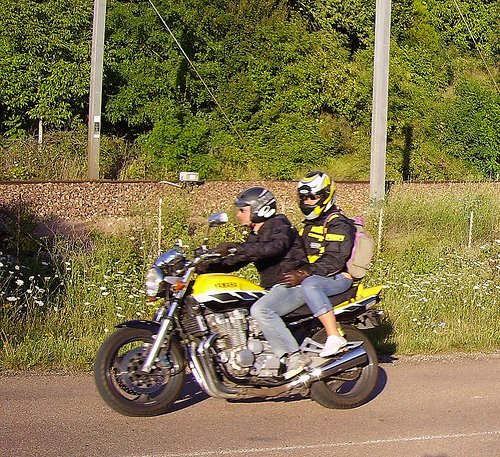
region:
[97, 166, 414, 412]
couple on a motorcycle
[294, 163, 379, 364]
woman with a brown backpack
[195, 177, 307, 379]
man in black helmet and blue jeans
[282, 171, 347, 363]
woman wearing brown leather gloves and blue jeans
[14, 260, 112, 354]
white flowers growing next to highway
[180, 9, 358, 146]
forest of green trees next to train tracks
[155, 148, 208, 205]
metal electrical box on the ground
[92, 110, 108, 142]
black and white sign on wooden pole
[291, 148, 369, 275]
woman in yellow and black motorcycle helmet and jacket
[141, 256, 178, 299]
shiny headlight on front of motorcycle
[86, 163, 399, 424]
A man and a woman are on a motorcycle.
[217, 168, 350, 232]
Both riders are wearing helmets.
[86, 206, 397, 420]
The motorcycle's colors are yellow and black.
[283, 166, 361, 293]
The woman's helmet and jacket colors match those of the motorcycle.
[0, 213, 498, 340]
Flowers are growing on the side of the road.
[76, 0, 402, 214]
Two poles are in the background.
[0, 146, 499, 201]
Railroad tracks are in the background.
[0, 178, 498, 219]
Gravel rocks are besides the tracks.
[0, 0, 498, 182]
Trees are in the background.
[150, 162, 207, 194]
A box of some kind is beside the railroad tracks.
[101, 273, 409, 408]
motorcycle on the road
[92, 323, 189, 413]
black with chrome motorcycle tire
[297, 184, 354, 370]
woman riding on back on motorcycle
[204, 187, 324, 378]
man riding a motorcycle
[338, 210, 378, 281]
tan and pink backpack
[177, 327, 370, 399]
chrome motorcycle muffler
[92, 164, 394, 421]
two people riding on a motorcycle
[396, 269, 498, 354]
small white wild flowers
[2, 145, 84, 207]
train rails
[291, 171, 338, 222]
woman's riding helmet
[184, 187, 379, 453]
Two people riding on a motorcycle.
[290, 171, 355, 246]
A person with a helmet on their head.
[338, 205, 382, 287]
The person on the back of the bike has on backpack.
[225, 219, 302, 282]
The man has on a black jacket.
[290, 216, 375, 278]
The lady has on a yellow and black jacket.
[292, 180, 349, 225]
The helmet is yellow and black.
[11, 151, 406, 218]
The tracks is on the other side of the road.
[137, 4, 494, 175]
A lot of trees and bushes on the side of the track.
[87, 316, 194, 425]
The motorcycle has a black wheel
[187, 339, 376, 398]
The muffler is long and chrome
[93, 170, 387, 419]
Motorcycle with two people on it.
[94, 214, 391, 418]
Yellow and black motorcycle.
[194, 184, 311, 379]
Motorcycle driver wearing protective helmet.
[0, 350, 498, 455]
Road.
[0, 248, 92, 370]
White flowers and tall grass.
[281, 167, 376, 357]
Passenger on the motorcycle wearing jeans and tennis shoes.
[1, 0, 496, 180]
Many trees covered with green leaves.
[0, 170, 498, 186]
Railroad tracks.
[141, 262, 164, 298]
Headlight.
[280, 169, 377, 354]
Passenger with a brown backpack.